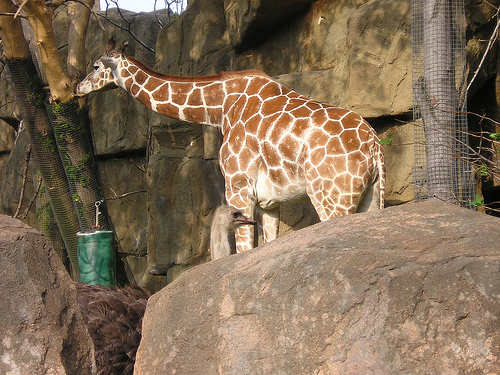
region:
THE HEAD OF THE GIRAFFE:
[81, 46, 129, 96]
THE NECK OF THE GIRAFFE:
[125, 57, 207, 127]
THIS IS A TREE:
[62, 106, 94, 213]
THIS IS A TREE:
[35, 98, 59, 200]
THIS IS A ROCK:
[346, 27, 390, 92]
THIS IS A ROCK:
[283, 258, 403, 322]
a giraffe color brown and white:
[58, 44, 400, 268]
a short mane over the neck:
[121, 51, 263, 88]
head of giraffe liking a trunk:
[1, 1, 171, 302]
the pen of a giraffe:
[0, 4, 499, 374]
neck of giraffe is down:
[65, 46, 245, 146]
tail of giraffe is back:
[362, 138, 394, 215]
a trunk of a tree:
[403, 1, 475, 208]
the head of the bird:
[198, 196, 260, 263]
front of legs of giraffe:
[223, 199, 286, 255]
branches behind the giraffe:
[53, 1, 228, 173]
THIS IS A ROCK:
[226, 301, 281, 356]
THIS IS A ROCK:
[17, 266, 42, 328]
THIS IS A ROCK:
[135, 159, 182, 226]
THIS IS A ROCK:
[335, 39, 399, 66]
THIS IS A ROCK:
[126, 22, 211, 64]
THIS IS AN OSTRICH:
[196, 188, 248, 272]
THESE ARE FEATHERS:
[91, 301, 123, 328]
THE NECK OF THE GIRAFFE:
[148, 79, 216, 117]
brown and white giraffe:
[117, 59, 387, 228]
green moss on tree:
[47, 91, 99, 185]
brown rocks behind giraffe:
[293, 16, 436, 128]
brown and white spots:
[175, 50, 390, 219]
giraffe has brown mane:
[140, 57, 255, 91]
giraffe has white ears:
[92, 44, 125, 79]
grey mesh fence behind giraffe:
[410, 18, 497, 185]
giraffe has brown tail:
[344, 144, 397, 224]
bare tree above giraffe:
[97, 0, 164, 46]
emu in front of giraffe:
[190, 194, 252, 267]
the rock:
[293, 240, 445, 357]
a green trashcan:
[73, 226, 126, 285]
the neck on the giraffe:
[132, 75, 182, 105]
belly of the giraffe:
[260, 170, 298, 193]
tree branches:
[103, 1, 159, 36]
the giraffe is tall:
[83, 50, 375, 214]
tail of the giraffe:
[376, 181, 391, 206]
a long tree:
[423, 26, 461, 201]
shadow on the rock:
[264, 33, 315, 70]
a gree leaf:
[461, 195, 485, 210]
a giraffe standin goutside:
[72, 63, 386, 258]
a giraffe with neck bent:
[62, 40, 460, 355]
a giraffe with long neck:
[101, 52, 236, 134]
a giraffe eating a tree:
[46, 36, 244, 153]